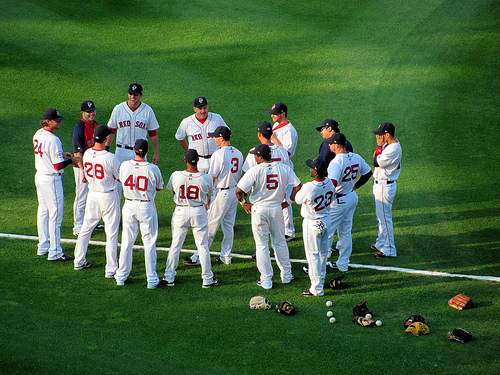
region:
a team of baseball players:
[90, 30, 370, 328]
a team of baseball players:
[157, 114, 305, 361]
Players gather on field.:
[14, 54, 426, 310]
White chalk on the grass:
[395, 250, 498, 290]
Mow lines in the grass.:
[358, 0, 443, 108]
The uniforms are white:
[11, 167, 393, 287]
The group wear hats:
[30, 80, 440, 205]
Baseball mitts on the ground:
[245, 288, 304, 318]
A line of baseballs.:
[316, 299, 341, 331]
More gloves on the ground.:
[399, 281, 479, 353]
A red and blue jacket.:
[70, 119, 100, 162]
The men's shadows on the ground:
[416, 167, 496, 294]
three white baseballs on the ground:
[320, 299, 336, 327]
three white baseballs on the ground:
[316, 294, 341, 332]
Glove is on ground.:
[441, 287, 486, 322]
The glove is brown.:
[422, 276, 492, 327]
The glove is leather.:
[423, 276, 498, 318]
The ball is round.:
[320, 294, 335, 310]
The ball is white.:
[319, 295, 336, 310]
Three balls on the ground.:
[320, 291, 347, 355]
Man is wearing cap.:
[21, 99, 73, 270]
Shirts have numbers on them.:
[21, 75, 381, 255]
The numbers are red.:
[29, 80, 387, 268]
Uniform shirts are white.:
[33, 105, 371, 311]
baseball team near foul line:
[40, 91, 386, 292]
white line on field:
[15, 219, 476, 308]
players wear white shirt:
[50, 129, 225, 194]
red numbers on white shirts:
[73, 141, 156, 196]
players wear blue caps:
[132, 122, 143, 177]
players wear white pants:
[162, 197, 218, 304]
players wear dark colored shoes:
[195, 270, 214, 294]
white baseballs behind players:
[295, 290, 420, 355]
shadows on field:
[145, 20, 421, 142]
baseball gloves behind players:
[303, 263, 490, 373]